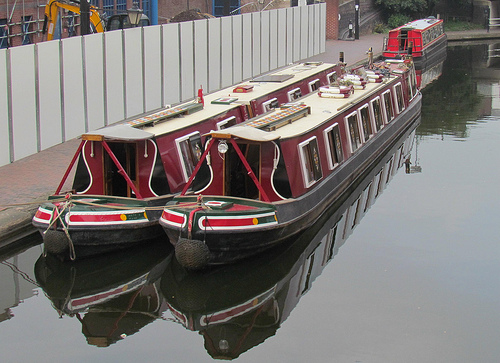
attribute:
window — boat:
[297, 139, 327, 182]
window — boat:
[328, 127, 344, 163]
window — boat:
[303, 138, 331, 185]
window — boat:
[302, 132, 329, 181]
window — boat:
[344, 111, 363, 155]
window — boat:
[181, 124, 211, 184]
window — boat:
[345, 107, 366, 145]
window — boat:
[341, 110, 371, 150]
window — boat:
[360, 100, 389, 150]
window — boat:
[381, 87, 399, 123]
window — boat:
[362, 104, 377, 134]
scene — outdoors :
[4, 5, 459, 361]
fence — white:
[6, 4, 328, 154]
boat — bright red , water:
[388, 8, 447, 62]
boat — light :
[212, 140, 235, 155]